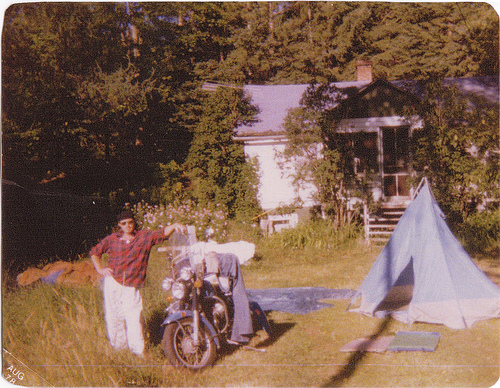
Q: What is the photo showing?
A: It is showing a forest.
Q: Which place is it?
A: It is a forest.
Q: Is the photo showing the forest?
A: Yes, it is showing the forest.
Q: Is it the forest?
A: Yes, it is the forest.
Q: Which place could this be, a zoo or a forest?
A: It is a forest.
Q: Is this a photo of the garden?
A: No, the picture is showing the forest.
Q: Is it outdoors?
A: Yes, it is outdoors.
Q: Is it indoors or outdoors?
A: It is outdoors.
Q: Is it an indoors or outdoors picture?
A: It is outdoors.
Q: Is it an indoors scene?
A: No, it is outdoors.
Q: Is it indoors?
A: No, it is outdoors.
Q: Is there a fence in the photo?
A: No, there are no fences.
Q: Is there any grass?
A: Yes, there is grass.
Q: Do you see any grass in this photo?
A: Yes, there is grass.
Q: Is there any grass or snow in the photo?
A: Yes, there is grass.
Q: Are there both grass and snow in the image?
A: No, there is grass but no snow.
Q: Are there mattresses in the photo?
A: No, there are no mattresses.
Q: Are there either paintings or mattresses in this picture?
A: No, there are no mattresses or paintings.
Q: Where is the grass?
A: The grass is on the ground.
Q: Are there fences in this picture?
A: No, there are no fences.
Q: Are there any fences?
A: No, there are no fences.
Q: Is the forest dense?
A: Yes, the forest is dense.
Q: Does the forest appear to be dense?
A: Yes, the forest is dense.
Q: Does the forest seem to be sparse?
A: No, the forest is dense.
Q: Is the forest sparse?
A: No, the forest is dense.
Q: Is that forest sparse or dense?
A: The forest is dense.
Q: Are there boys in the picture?
A: No, there are no boys.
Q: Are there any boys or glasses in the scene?
A: No, there are no boys or glasses.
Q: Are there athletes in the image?
A: No, there are no athletes.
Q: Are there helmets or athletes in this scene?
A: No, there are no athletes or helmets.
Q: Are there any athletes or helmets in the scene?
A: No, there are no athletes or helmets.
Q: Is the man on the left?
A: Yes, the man is on the left of the image.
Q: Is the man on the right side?
A: No, the man is on the left of the image.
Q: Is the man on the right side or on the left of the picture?
A: The man is on the left of the image.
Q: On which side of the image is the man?
A: The man is on the left of the image.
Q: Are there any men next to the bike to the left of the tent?
A: Yes, there is a man next to the bike.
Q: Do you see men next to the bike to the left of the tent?
A: Yes, there is a man next to the bike.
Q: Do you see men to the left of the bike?
A: Yes, there is a man to the left of the bike.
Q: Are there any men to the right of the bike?
A: No, the man is to the left of the bike.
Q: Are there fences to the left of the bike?
A: No, there is a man to the left of the bike.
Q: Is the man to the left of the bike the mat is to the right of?
A: Yes, the man is to the left of the bike.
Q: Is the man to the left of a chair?
A: No, the man is to the left of the bike.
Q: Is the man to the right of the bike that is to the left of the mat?
A: No, the man is to the left of the bike.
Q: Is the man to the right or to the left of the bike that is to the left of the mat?
A: The man is to the left of the bike.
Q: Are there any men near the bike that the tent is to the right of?
A: Yes, there is a man near the bike.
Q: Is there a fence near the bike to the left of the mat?
A: No, there is a man near the bike.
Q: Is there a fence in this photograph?
A: No, there are no fences.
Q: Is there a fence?
A: No, there are no fences.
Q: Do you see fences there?
A: No, there are no fences.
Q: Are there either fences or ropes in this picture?
A: No, there are no fences or ropes.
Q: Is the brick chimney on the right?
A: Yes, the chimney is on the right of the image.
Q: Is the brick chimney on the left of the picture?
A: No, the chimney is on the right of the image.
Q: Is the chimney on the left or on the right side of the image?
A: The chimney is on the right of the image.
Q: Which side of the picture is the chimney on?
A: The chimney is on the right of the image.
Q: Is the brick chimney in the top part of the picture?
A: Yes, the chimney is in the top of the image.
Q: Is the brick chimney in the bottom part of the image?
A: No, the chimney is in the top of the image.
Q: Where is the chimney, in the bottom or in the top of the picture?
A: The chimney is in the top of the image.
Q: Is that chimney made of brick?
A: Yes, the chimney is made of brick.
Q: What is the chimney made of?
A: The chimney is made of brick.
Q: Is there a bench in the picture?
A: No, there are no benches.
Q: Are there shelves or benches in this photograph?
A: No, there are no benches or shelves.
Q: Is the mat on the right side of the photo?
A: Yes, the mat is on the right of the image.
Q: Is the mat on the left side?
A: No, the mat is on the right of the image.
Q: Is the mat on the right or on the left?
A: The mat is on the right of the image.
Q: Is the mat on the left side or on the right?
A: The mat is on the right of the image.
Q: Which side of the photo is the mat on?
A: The mat is on the right of the image.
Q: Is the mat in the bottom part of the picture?
A: Yes, the mat is in the bottom of the image.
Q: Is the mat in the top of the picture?
A: No, the mat is in the bottom of the image.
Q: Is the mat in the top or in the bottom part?
A: The mat is in the bottom of the image.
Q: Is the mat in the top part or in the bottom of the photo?
A: The mat is in the bottom of the image.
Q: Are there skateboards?
A: No, there are no skateboards.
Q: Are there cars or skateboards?
A: No, there are no skateboards or cars.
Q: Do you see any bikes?
A: Yes, there is a bike.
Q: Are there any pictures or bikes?
A: Yes, there is a bike.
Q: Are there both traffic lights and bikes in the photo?
A: No, there is a bike but no traffic lights.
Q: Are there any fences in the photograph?
A: No, there are no fences.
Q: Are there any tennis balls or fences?
A: No, there are no fences or tennis balls.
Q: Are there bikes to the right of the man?
A: Yes, there is a bike to the right of the man.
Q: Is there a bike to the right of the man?
A: Yes, there is a bike to the right of the man.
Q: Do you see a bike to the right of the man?
A: Yes, there is a bike to the right of the man.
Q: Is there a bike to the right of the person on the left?
A: Yes, there is a bike to the right of the man.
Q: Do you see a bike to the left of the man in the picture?
A: No, the bike is to the right of the man.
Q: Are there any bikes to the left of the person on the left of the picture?
A: No, the bike is to the right of the man.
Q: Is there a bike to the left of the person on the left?
A: No, the bike is to the right of the man.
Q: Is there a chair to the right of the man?
A: No, there is a bike to the right of the man.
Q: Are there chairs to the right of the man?
A: No, there is a bike to the right of the man.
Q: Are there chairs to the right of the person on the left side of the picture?
A: No, there is a bike to the right of the man.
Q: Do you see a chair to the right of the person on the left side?
A: No, there is a bike to the right of the man.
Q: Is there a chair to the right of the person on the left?
A: No, there is a bike to the right of the man.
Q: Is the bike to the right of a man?
A: Yes, the bike is to the right of a man.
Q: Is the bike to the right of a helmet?
A: No, the bike is to the right of a man.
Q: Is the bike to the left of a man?
A: No, the bike is to the right of a man.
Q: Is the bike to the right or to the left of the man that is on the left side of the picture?
A: The bike is to the right of the man.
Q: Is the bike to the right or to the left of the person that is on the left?
A: The bike is to the right of the man.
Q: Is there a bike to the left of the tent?
A: Yes, there is a bike to the left of the tent.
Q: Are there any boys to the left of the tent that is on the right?
A: No, there is a bike to the left of the tent.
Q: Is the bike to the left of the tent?
A: Yes, the bike is to the left of the tent.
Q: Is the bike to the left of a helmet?
A: No, the bike is to the left of the tent.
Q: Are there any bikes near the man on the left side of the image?
A: Yes, there is a bike near the man.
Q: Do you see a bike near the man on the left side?
A: Yes, there is a bike near the man.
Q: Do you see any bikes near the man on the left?
A: Yes, there is a bike near the man.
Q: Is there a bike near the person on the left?
A: Yes, there is a bike near the man.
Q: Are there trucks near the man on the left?
A: No, there is a bike near the man.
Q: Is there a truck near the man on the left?
A: No, there is a bike near the man.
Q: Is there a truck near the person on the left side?
A: No, there is a bike near the man.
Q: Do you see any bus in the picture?
A: No, there are no buses.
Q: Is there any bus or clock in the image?
A: No, there are no buses or clocks.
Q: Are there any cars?
A: No, there are no cars.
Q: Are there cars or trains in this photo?
A: No, there are no cars or trains.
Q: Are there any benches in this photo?
A: No, there are no benches.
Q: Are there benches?
A: No, there are no benches.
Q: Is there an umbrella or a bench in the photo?
A: No, there are no benches or umbrellas.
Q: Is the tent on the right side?
A: Yes, the tent is on the right of the image.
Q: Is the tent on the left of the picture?
A: No, the tent is on the right of the image.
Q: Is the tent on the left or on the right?
A: The tent is on the right of the image.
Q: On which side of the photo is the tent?
A: The tent is on the right of the image.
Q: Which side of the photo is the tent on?
A: The tent is on the right of the image.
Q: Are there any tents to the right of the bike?
A: Yes, there is a tent to the right of the bike.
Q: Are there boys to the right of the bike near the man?
A: No, there is a tent to the right of the bike.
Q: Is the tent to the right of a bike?
A: Yes, the tent is to the right of a bike.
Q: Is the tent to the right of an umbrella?
A: No, the tent is to the right of a bike.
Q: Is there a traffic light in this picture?
A: No, there are no traffic lights.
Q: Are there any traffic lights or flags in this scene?
A: No, there are no traffic lights or flags.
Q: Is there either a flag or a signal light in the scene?
A: No, there are no traffic lights or flags.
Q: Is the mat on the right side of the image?
A: Yes, the mat is on the right of the image.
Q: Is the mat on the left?
A: No, the mat is on the right of the image.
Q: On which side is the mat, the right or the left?
A: The mat is on the right of the image.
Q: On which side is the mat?
A: The mat is on the right of the image.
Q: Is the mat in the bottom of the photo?
A: Yes, the mat is in the bottom of the image.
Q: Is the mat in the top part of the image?
A: No, the mat is in the bottom of the image.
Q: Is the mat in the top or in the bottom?
A: The mat is in the bottom of the image.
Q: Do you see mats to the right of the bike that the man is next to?
A: Yes, there is a mat to the right of the bike.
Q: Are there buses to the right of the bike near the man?
A: No, there is a mat to the right of the bike.